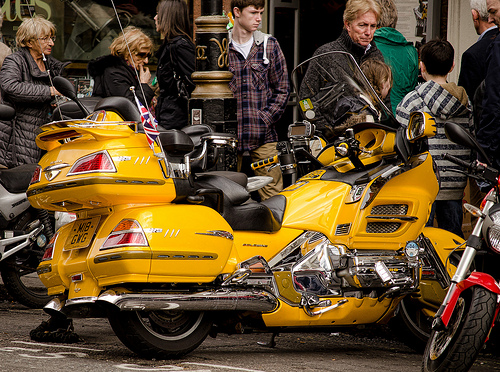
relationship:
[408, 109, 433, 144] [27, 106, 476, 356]
mirror on motorcycle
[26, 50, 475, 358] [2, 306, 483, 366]
bike parked in parking space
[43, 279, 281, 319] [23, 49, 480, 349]
pipe on bike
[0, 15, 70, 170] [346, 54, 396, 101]
person has head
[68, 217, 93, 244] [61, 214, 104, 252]
letters on license plate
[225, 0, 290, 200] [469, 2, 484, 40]
boy has head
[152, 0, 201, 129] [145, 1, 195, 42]
woman has head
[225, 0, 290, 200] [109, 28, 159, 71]
boy has head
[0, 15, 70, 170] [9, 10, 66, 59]
person has head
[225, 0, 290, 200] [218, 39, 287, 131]
boy with jacket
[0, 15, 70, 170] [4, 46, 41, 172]
person with jacket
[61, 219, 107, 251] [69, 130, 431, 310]
license plate on back of motorcycle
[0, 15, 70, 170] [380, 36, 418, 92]
person with jacket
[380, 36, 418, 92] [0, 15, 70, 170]
jacket on person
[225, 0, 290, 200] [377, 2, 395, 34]
boy has head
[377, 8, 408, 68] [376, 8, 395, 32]
person has head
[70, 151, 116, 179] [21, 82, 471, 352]
brake light on bike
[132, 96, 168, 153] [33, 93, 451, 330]
flag on bike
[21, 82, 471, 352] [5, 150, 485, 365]
bike on street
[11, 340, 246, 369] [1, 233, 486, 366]
paint on street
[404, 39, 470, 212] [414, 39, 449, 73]
boy has hair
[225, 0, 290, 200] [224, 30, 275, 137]
boy in sweatshirt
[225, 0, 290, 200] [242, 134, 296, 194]
boy in pants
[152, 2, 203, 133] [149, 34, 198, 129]
woman in jacket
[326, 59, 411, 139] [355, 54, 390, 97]
girl has hair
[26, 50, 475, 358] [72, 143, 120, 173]
bike has light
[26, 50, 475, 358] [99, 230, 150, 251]
bike has tail light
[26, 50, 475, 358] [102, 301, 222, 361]
bike has tire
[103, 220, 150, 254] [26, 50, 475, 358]
tail light on bike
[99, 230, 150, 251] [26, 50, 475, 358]
tail light on bike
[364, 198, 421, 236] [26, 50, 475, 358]
side vent on bike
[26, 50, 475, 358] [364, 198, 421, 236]
bike has a side vent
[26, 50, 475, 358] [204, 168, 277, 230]
bike has a seat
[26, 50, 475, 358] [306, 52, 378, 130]
bike has a front windshield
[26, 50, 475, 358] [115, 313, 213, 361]
bike has a rear wheel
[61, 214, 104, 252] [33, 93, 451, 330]
license plate on bike